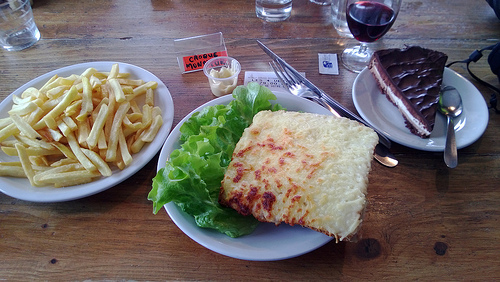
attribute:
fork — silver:
[253, 37, 401, 174]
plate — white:
[10, 58, 175, 200]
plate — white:
[341, 44, 493, 156]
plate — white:
[168, 84, 368, 261]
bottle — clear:
[5, 4, 42, 51]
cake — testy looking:
[365, 42, 474, 140]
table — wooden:
[10, 4, 499, 265]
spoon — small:
[437, 84, 462, 172]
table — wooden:
[6, 204, 161, 277]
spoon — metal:
[440, 84, 464, 174]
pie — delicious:
[373, 46, 445, 137]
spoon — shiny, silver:
[408, 67, 480, 176]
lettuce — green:
[140, 76, 294, 241]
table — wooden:
[401, 200, 481, 273]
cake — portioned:
[405, 97, 435, 138]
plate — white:
[212, 237, 298, 264]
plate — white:
[72, 180, 100, 214]